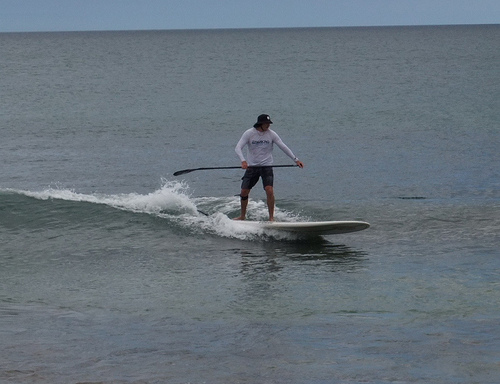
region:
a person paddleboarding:
[164, 96, 419, 272]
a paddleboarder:
[191, 91, 414, 241]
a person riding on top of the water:
[163, 76, 415, 250]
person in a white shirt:
[171, 104, 383, 253]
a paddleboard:
[178, 196, 428, 284]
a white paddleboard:
[146, 188, 409, 285]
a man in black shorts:
[212, 80, 347, 252]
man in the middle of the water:
[23, 42, 485, 342]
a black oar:
[131, 139, 361, 183]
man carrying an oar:
[139, 113, 439, 259]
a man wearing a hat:
[238, 105, 304, 221]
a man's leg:
[261, 167, 276, 220]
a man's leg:
[232, 163, 258, 219]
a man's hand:
[270, 135, 305, 173]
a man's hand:
[228, 128, 249, 170]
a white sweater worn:
[234, 127, 297, 172]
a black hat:
[253, 110, 275, 126]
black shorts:
[240, 165, 279, 185]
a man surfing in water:
[157, 99, 374, 240]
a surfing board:
[193, 211, 370, 242]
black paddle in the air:
[162, 161, 319, 177]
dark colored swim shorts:
[237, 158, 288, 190]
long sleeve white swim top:
[232, 119, 307, 174]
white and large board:
[196, 210, 386, 257]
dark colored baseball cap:
[251, 105, 277, 127]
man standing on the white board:
[219, 94, 294, 218]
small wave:
[342, 191, 495, 231]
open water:
[52, 42, 477, 97]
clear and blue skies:
[1, 1, 476, 25]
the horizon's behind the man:
[7, 14, 497, 39]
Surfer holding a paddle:
[157, 103, 389, 258]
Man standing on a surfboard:
[220, 95, 310, 231]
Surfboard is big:
[151, 205, 371, 250]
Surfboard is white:
[168, 205, 377, 247]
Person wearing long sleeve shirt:
[225, 105, 310, 230]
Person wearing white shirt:
[222, 108, 308, 225]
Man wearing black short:
[228, 105, 314, 225]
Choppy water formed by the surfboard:
[12, 167, 219, 240]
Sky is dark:
[0, 0, 497, 30]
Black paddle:
[166, 160, 311, 185]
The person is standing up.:
[166, 98, 336, 231]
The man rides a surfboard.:
[155, 99, 387, 261]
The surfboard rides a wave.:
[19, 177, 309, 246]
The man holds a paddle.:
[157, 148, 313, 190]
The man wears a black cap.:
[243, 95, 285, 138]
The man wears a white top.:
[219, 125, 309, 173]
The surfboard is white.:
[185, 206, 386, 243]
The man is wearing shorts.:
[235, 157, 281, 191]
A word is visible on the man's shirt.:
[238, 134, 277, 150]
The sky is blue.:
[1, 0, 498, 41]